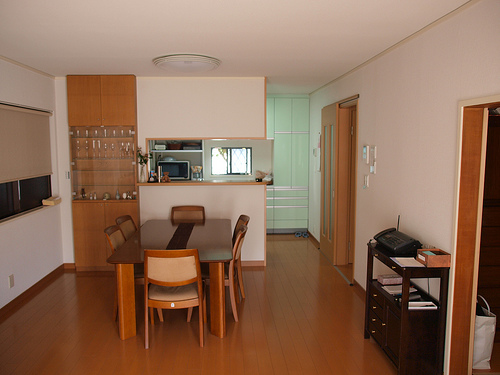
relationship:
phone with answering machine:
[375, 228, 397, 239] [372, 213, 423, 257]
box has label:
[416, 247, 452, 267] [416, 254, 426, 261]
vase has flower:
[140, 165, 147, 183] [138, 151, 148, 164]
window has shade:
[0, 99, 53, 221] [1, 100, 52, 184]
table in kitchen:
[106, 218, 233, 340] [56, 81, 265, 352]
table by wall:
[363, 236, 449, 375] [306, 0, 499, 373]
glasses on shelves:
[68, 125, 137, 156] [70, 125, 139, 199]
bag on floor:
[474, 293, 498, 371] [1, 233, 499, 375]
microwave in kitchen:
[157, 159, 191, 180] [56, 81, 265, 352]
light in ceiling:
[152, 53, 220, 74] [0, 2, 474, 96]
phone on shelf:
[375, 228, 397, 239] [366, 234, 450, 270]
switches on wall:
[360, 145, 378, 186] [306, 0, 499, 373]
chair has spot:
[143, 249, 206, 349] [170, 301, 176, 307]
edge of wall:
[311, 2, 471, 94] [306, 0, 499, 373]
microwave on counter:
[157, 159, 191, 180] [138, 177, 263, 185]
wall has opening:
[59, 77, 267, 269] [145, 139, 267, 184]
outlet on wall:
[9, 274, 16, 288] [0, 59, 61, 318]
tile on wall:
[266, 92, 312, 234] [267, 94, 312, 235]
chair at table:
[143, 249, 206, 349] [106, 218, 233, 340]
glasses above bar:
[68, 125, 137, 156] [73, 184, 137, 200]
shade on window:
[1, 100, 52, 184] [0, 99, 53, 221]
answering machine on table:
[372, 213, 423, 257] [363, 236, 449, 375]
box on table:
[416, 247, 452, 267] [363, 236, 449, 375]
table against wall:
[106, 218, 233, 340] [306, 0, 499, 373]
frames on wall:
[360, 143, 379, 189] [306, 0, 499, 373]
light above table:
[152, 53, 220, 74] [106, 218, 233, 340]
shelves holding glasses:
[70, 125, 139, 199] [68, 125, 137, 156]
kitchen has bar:
[56, 81, 265, 352] [73, 184, 137, 200]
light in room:
[152, 53, 220, 74] [0, 1, 499, 373]